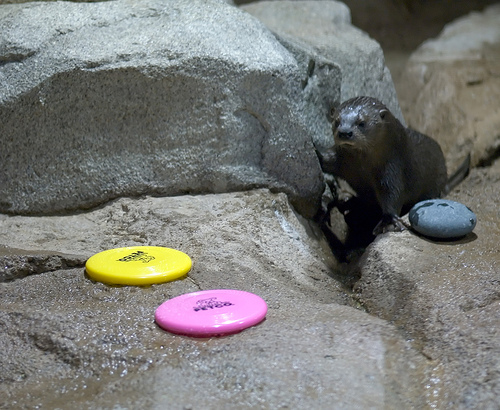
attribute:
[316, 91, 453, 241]
otter — black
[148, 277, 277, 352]
frisbee — purple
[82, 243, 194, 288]
frisbee — yellow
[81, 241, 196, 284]
frisbee — pink and yellow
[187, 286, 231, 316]
words — black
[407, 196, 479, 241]
rock — black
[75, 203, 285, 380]
frisbee — circular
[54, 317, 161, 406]
stones — wet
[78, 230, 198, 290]
frisbee — yellow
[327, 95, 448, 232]
otter — wet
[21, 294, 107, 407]
rock — wet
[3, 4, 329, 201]
stone — grey